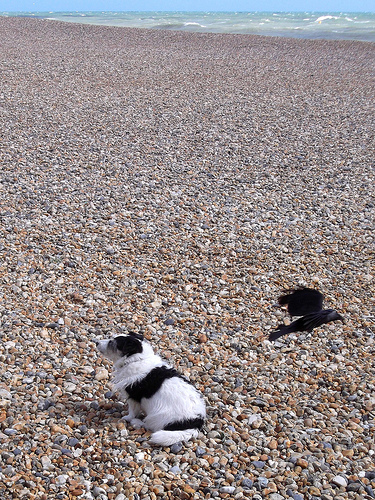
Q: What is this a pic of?
A: A dog on the beach.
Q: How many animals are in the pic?
A: 2.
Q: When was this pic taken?
A: During the daytime.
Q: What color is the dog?
A: White and black.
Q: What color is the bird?
A: Black.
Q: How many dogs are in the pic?
A: 1.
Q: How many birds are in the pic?
A: One.